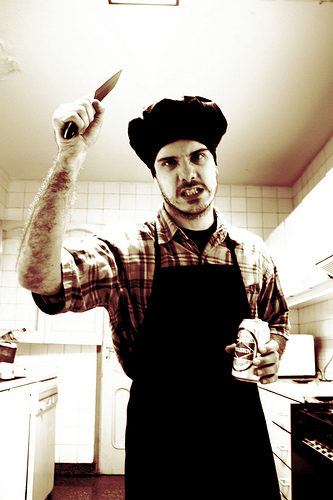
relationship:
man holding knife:
[15, 93, 292, 499] [57, 67, 124, 142]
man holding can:
[15, 93, 292, 499] [230, 316, 274, 380]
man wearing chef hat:
[15, 93, 292, 499] [124, 94, 229, 171]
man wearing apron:
[15, 93, 292, 499] [122, 222, 282, 499]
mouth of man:
[179, 184, 204, 199] [15, 93, 292, 499]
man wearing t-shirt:
[15, 93, 292, 499] [178, 222, 219, 251]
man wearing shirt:
[15, 93, 292, 499] [29, 203, 290, 382]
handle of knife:
[62, 102, 98, 142] [57, 67, 124, 142]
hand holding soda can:
[222, 340, 281, 385] [230, 316, 274, 380]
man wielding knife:
[15, 93, 292, 499] [57, 67, 124, 142]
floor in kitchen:
[47, 474, 125, 499] [0, 0, 332, 499]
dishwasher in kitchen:
[26, 384, 61, 499] [0, 0, 332, 499]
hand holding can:
[222, 340, 281, 385] [230, 316, 274, 380]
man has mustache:
[15, 93, 292, 499] [173, 182, 209, 192]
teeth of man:
[185, 189, 201, 197] [15, 93, 292, 499]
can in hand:
[230, 316, 274, 380] [222, 340, 281, 385]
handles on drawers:
[274, 412, 288, 487] [269, 399, 293, 499]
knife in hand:
[57, 67, 124, 142] [52, 98, 104, 145]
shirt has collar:
[29, 203, 290, 382] [155, 206, 231, 252]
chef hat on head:
[124, 94, 229, 171] [152, 138, 220, 213]